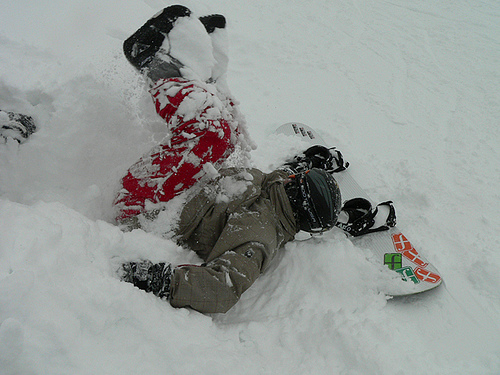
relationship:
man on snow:
[117, 19, 348, 341] [47, 221, 352, 360]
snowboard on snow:
[268, 114, 433, 307] [47, 221, 352, 360]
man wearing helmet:
[117, 19, 348, 341] [286, 167, 342, 241]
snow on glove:
[47, 221, 352, 360] [115, 256, 174, 293]